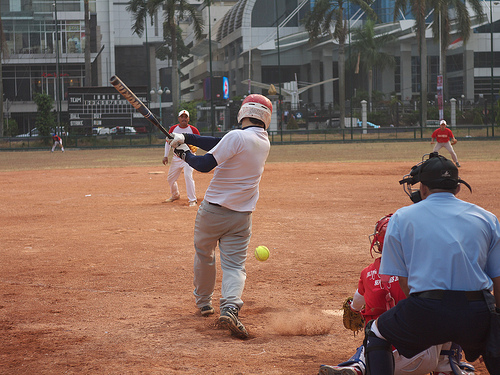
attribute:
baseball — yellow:
[250, 240, 274, 265]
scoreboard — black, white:
[60, 83, 162, 138]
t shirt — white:
[201, 125, 271, 213]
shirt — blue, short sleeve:
[382, 191, 497, 293]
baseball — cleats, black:
[240, 233, 299, 283]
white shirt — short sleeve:
[180, 129, 280, 214]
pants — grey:
[190, 199, 253, 309]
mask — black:
[404, 145, 481, 203]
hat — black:
[413, 151, 463, 191]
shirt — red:
[425, 127, 454, 144]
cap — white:
[218, 87, 305, 131]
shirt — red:
[430, 127, 452, 142]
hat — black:
[410, 157, 464, 196]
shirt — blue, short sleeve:
[370, 192, 497, 297]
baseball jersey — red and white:
[104, 72, 190, 152]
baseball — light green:
[252, 242, 271, 262]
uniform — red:
[354, 254, 446, 369]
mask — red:
[369, 214, 394, 256]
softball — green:
[249, 240, 272, 264]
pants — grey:
[196, 196, 255, 315]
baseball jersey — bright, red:
[429, 124, 456, 145]